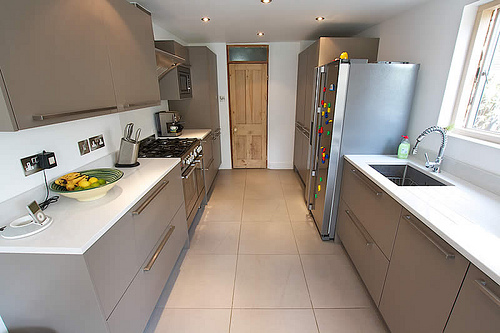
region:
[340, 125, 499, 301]
sterile white kitchen counter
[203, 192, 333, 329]
large beige tiles on floor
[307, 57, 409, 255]
stainless steel refrigerator with colored magnets on it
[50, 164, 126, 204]
green and beige bowl of fruit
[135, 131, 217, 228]
stainless steel oven and range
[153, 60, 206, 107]
microwave hanging on wall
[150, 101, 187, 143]
coffee maker on counter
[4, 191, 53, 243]
Ipod player on charger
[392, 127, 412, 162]
dish washing detergent next to sink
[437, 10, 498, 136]
large open window letting in light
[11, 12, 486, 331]
steel colored kitchen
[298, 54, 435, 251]
steel fridge with a lot of magnets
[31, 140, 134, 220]
fruit dish on kitchen counter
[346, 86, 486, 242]
kitchen sink with soap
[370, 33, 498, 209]
kitchen window behind a sink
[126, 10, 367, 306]
wooden entry door to kitchen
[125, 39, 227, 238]
stainless steel range and cover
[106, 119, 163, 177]
steel colored knife set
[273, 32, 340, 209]
large pantry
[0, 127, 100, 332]
ipod on counter charging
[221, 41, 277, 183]
door in a room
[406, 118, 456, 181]
faucet on a sink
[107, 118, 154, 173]
knives on a counter top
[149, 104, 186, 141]
coffee maker on a counter top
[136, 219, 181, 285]
handle on a drawer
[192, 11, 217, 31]
recessed light in a ceiling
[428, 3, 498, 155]
window in a wall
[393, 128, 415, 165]
bottle on a counter top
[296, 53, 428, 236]
refrigerator in a kitchen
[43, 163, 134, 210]
bowl on a counter top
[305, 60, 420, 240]
Refrigerator with magnets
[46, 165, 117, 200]
Large bowl of fruit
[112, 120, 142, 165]
Knife set on counter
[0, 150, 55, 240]
ipod docked and charging on counter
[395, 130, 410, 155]
Hand soap on counter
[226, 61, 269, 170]
Back door is brown and wood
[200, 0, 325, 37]
Ceiling lights are recessed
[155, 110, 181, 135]
Coffee maker on counter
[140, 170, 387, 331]
Floor is tan tiles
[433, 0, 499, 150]
Natural light is bright from window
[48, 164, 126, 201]
bowl of fruit on kitchen counter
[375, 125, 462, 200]
kitchen sink with high faucet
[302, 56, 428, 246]
stainless steel refrigerator with double doors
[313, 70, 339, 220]
magnets on front of refrigerator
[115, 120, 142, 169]
kitchen knives in holder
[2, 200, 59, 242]
mp3 player in stand/speaker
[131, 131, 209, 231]
stainless steel gas range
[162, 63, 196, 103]
microwave above range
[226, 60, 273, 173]
wooden door at end of kitchen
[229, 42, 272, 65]
transom over door in kitchen